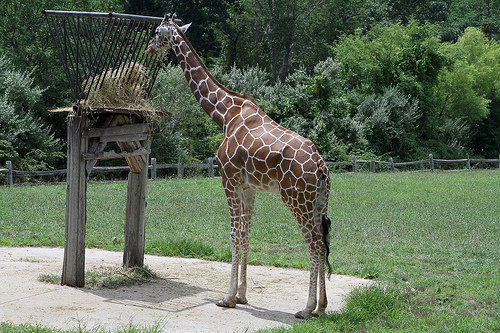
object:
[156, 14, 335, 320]
giraffe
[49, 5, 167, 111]
feeding bin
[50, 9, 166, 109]
cage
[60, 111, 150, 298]
stand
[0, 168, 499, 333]
meadow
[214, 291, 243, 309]
feet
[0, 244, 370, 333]
concrete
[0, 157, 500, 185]
fence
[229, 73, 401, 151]
bushes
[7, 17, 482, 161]
background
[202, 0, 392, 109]
trees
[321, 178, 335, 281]
tail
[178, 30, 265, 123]
mane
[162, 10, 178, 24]
horns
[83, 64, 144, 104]
hay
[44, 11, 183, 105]
basket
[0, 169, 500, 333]
grass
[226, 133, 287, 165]
spots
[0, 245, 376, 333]
sand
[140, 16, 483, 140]
woods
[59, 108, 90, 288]
poles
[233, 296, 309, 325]
shadow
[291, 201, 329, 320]
legs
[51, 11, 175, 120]
container